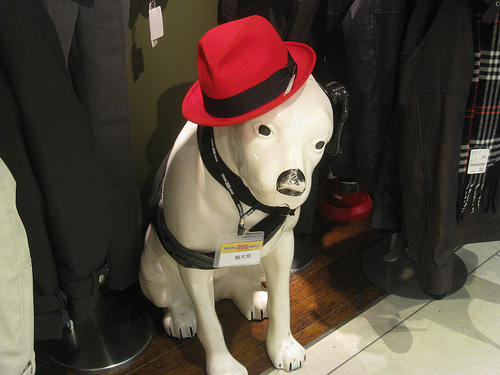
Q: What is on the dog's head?
A: The red hat.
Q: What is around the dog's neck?
A: A lanyard.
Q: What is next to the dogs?
A: Jackets.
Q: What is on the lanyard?
A: A nametag.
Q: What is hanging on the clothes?
A: Price tags.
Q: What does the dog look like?
A: Happy.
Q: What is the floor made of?
A: Wood and tile.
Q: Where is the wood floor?
A: Under dog.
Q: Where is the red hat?
A: On dog.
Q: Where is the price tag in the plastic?
A: Around dog's neck.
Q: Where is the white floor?
A: In front of dog.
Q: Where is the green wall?
A: Behind dog.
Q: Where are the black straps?
A: On dog.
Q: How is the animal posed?
A: Sitting.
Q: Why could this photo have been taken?
A: Advertisement.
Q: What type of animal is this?
A: Dog.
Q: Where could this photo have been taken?
A: Clothing store.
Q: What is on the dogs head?
A: Hat.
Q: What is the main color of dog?
A: White.